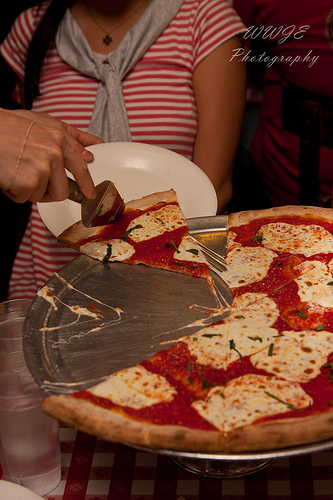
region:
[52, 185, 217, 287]
a slice of pizza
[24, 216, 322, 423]
a pizza with sauce and cheese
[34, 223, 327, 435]
a pizza on a tray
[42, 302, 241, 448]
a slice of margarita pizza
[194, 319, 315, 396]
cut up pieces of basil on a pizza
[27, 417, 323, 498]
a checkered table cloth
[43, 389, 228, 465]
the crust of a slice of pizza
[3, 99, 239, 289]
a person serving a slice of pizza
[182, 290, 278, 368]
mozzarella cheese on the pizza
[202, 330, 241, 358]
green stuff on the pizza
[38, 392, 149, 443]
brown pizza crust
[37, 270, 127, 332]
white cheese on the silver tray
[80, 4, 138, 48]
necklace on the woman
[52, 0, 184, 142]
gray scarf on the woman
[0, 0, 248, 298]
red and white striped shirt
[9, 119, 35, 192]
rubber band on the hand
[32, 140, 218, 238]
white plate with a slice of pizza on it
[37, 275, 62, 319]
Cheese stuck on the side of pan.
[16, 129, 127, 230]
Hand holding pizza cutter.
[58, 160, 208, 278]
slice of pizza being placed on plate.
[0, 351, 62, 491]
Cup of water in corner on table.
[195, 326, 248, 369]
Mozzarella cheese with sprinkles of basil.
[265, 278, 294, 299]
Red sauce on pizza.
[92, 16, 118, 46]
necklace around woman's neck.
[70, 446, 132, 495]
red and white checkered table cloth.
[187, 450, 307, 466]
Edge of silver pizza pan.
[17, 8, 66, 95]
Woman's hair off to the side.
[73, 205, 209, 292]
a slice of pizza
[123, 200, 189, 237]
some cheese on a pizza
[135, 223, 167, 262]
some sauce on a pizza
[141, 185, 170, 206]
a piece of crust on a pizza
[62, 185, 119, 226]
a silver colored pizza cutter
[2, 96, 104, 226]
a hand holding a pizza cutter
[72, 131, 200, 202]
a small white china plate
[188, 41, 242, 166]
the arm of a woman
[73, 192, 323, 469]
a pan with a pizza on it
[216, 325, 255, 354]
cheese on the pizza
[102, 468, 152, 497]
a table cloth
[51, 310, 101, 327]
cheese on the pizza pan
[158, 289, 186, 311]
the pizza pan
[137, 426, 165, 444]
the crust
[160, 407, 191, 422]
the sauce is red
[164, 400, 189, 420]
the red sauce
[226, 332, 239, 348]
green spices on the pizza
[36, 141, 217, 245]
small round white plate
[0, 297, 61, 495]
tall clear glass cup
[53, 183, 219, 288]
pizza on the plate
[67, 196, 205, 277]
pizza has cheese on it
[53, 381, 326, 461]
pizza has crust on it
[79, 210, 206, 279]
sauce is red in color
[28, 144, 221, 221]
plate is white in color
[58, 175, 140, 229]
spatula is serving the pizza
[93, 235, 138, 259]
white cheese and red sauce on pizza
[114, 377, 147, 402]
white cheese and red sauce on pizza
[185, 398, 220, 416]
white cheese and red sauce on pizza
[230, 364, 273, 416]
white cheese and red sauce on pizza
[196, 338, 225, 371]
white cheese and red sauce on pizza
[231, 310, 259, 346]
white cheese and red sauce on pizza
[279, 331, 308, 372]
white cheese and red sauce on pizza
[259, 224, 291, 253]
white cheese and red sauce on pizza